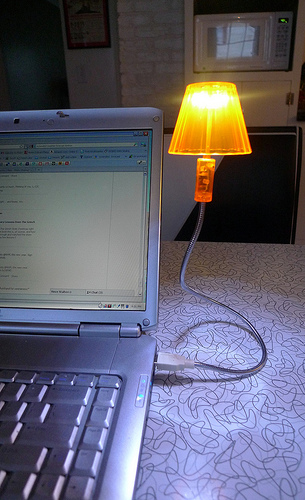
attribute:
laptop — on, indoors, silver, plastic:
[1, 105, 165, 498]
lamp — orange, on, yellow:
[156, 81, 266, 378]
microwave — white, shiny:
[194, 12, 292, 74]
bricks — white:
[117, 1, 186, 128]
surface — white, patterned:
[131, 239, 304, 499]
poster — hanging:
[62, 0, 111, 49]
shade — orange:
[167, 81, 251, 156]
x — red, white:
[142, 129, 150, 137]